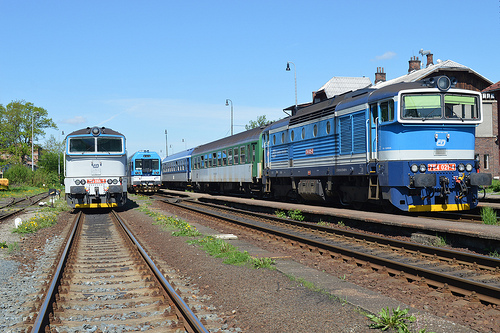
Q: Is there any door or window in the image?
A: Yes, there is a window.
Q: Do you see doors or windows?
A: Yes, there is a window.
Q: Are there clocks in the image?
A: No, there are no clocks.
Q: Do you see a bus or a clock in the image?
A: No, there are no clocks or buses.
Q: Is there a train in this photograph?
A: Yes, there is a train.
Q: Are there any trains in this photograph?
A: Yes, there is a train.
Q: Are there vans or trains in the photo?
A: Yes, there is a train.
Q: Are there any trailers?
A: No, there are no trailers.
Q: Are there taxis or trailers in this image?
A: No, there are no trailers or taxis.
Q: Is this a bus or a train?
A: This is a train.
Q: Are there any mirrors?
A: No, there are no mirrors.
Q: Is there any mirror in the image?
A: No, there are no mirrors.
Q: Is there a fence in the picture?
A: No, there are no fences.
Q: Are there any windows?
A: Yes, there are windows.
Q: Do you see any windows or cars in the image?
A: Yes, there are windows.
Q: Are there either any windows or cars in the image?
A: Yes, there are windows.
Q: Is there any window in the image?
A: Yes, there is a window.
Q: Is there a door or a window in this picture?
A: Yes, there is a window.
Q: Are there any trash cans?
A: No, there are no trash cans.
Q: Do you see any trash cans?
A: No, there are no trash cans.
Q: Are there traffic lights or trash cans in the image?
A: No, there are no trash cans or traffic lights.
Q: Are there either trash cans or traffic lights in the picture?
A: No, there are no trash cans or traffic lights.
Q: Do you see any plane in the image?
A: No, there are no airplanes.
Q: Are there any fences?
A: No, there are no fences.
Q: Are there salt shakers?
A: No, there are no salt shakers.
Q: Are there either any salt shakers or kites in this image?
A: No, there are no salt shakers or kites.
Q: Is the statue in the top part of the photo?
A: Yes, the statue is in the top of the image.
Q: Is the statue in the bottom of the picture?
A: No, the statue is in the top of the image.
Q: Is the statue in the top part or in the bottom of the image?
A: The statue is in the top of the image.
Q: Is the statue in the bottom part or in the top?
A: The statue is in the top of the image.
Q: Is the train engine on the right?
A: Yes, the train engine is on the right of the image.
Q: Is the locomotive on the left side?
A: No, the locomotive is on the right of the image.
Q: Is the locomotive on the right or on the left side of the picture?
A: The locomotive is on the right of the image.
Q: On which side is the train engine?
A: The train engine is on the right of the image.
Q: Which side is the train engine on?
A: The train engine is on the right of the image.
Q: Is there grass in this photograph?
A: Yes, there is grass.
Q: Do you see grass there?
A: Yes, there is grass.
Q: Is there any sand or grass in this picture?
A: Yes, there is grass.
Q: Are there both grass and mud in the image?
A: No, there is grass but no mud.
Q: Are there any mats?
A: No, there are no mats.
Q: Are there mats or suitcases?
A: No, there are no mats or suitcases.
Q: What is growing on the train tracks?
A: The grass is growing on the train tracks.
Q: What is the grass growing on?
A: The grass is growing on the train tracks.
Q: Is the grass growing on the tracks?
A: Yes, the grass is growing on the tracks.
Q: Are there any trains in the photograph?
A: Yes, there is a train.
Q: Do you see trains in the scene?
A: Yes, there is a train.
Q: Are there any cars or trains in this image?
A: Yes, there is a train.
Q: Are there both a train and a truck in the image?
A: No, there is a train but no trucks.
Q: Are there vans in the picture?
A: No, there are no vans.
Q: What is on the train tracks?
A: The train is on the train tracks.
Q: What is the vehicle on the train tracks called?
A: The vehicle is a train.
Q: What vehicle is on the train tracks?
A: The vehicle is a train.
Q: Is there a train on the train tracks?
A: Yes, there is a train on the train tracks.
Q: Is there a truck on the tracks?
A: No, there is a train on the tracks.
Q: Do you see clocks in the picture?
A: No, there are no clocks.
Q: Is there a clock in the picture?
A: No, there are no clocks.